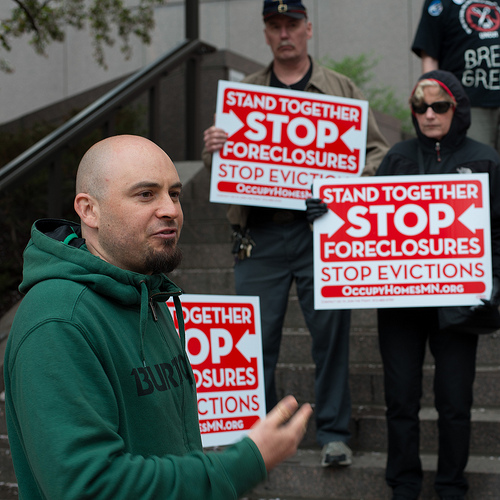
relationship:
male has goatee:
[0, 131, 314, 499] [137, 242, 184, 271]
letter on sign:
[322, 183, 334, 205] [311, 173, 491, 309]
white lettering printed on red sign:
[221, 90, 361, 120] [208, 78, 370, 211]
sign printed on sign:
[311, 172, 493, 311] [311, 173, 491, 309]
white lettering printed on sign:
[169, 302, 252, 386] [166, 288, 270, 449]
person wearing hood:
[375, 69, 500, 499] [381, 53, 482, 172]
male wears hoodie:
[0, 131, 314, 499] [0, 215, 270, 499]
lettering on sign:
[319, 185, 484, 254] [263, 172, 456, 292]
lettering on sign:
[223, 139, 357, 171] [206, 76, 370, 216]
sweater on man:
[39, 269, 169, 409] [1, 102, 277, 411]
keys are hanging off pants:
[228, 228, 255, 260] [236, 213, 353, 443]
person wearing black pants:
[375, 69, 500, 499] [377, 308, 479, 497]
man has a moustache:
[200, 0, 390, 469] [268, 36, 298, 50]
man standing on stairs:
[202, 0, 391, 469] [3, 157, 499, 499]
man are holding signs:
[202, 0, 391, 469] [147, 83, 498, 457]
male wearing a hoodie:
[0, 131, 314, 499] [0, 218, 267, 498]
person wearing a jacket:
[375, 69, 500, 499] [305, 64, 490, 223]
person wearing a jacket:
[375, 69, 500, 499] [371, 136, 498, 336]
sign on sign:
[311, 172, 493, 311] [311, 173, 491, 309]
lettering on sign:
[324, 237, 481, 257] [311, 173, 491, 309]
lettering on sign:
[188, 306, 250, 325] [155, 294, 265, 451]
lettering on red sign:
[223, 139, 360, 172] [208, 78, 370, 211]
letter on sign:
[429, 202, 456, 235] [311, 173, 491, 309]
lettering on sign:
[322, 183, 479, 204] [311, 173, 491, 309]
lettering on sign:
[320, 187, 483, 297] [311, 173, 491, 309]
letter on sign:
[346, 203, 371, 237] [311, 173, 491, 309]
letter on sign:
[368, 203, 395, 236] [311, 173, 491, 309]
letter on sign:
[394, 204, 426, 235] [311, 173, 491, 309]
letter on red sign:
[243, 110, 268, 142] [208, 78, 370, 211]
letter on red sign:
[264, 112, 287, 143] [208, 78, 370, 211]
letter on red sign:
[287, 117, 315, 147] [208, 78, 370, 211]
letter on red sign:
[316, 119, 338, 149] [208, 78, 370, 211]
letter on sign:
[209, 327, 234, 364] [155, 294, 265, 451]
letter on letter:
[178, 327, 212, 364] [346, 203, 371, 237]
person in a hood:
[375, 69, 500, 499] [303, 69, 498, 337]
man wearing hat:
[200, 0, 390, 469] [261, 0, 310, 22]